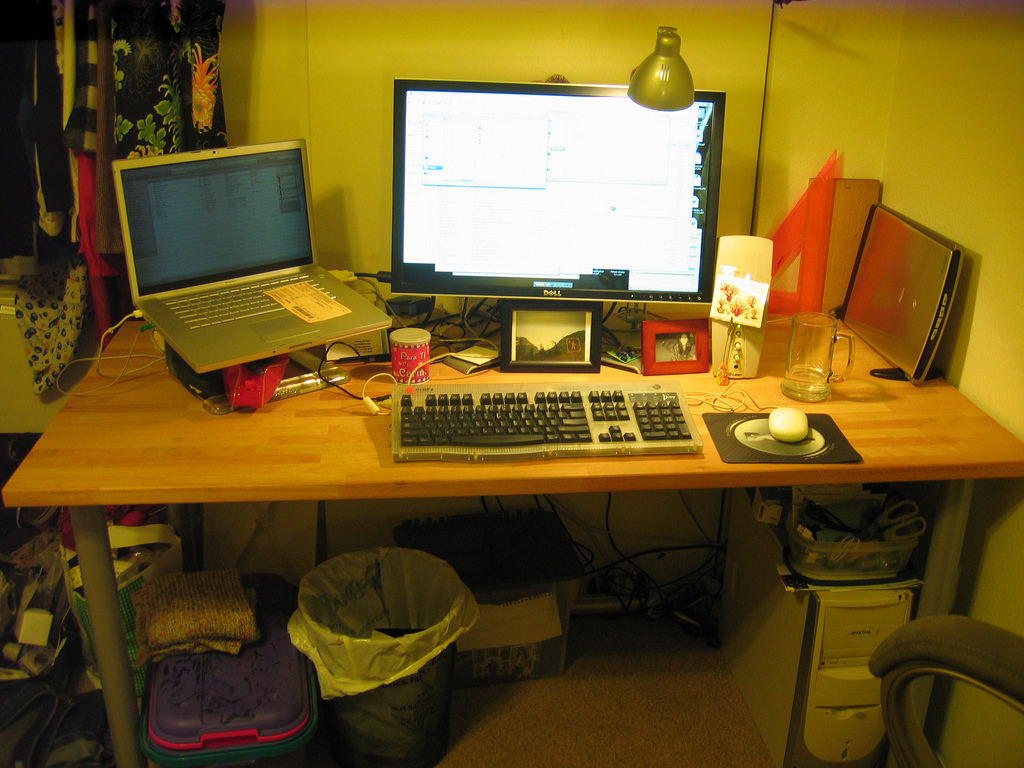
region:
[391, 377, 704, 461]
an extended computer keyboard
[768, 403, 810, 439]
an Apple Mighty Mouse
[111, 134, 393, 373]
an open laptop computer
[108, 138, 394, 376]
an Apple MacBook Pro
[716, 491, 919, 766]
a white desktop tower PC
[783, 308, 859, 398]
a clear glass mug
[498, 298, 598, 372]
a black framed photo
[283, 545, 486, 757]
trash bag in the garbage can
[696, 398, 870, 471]
mouse is on a mousepad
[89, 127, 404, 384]
laptop is silver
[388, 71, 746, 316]
computer monitor is on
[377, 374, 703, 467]
black keys on a silver keyboard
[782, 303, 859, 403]
empty glass that has a handle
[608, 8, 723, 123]
lamp is hanging over the monitor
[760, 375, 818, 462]
a white mighty mouse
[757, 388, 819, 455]
a white computer mouse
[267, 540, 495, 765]
this is a wastebasket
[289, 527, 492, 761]
there is a plastic bag in the wastebasket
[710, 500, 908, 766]
this is an old computer tower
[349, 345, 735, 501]
the keyboard has black keys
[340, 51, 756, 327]
a widescreen computer monitor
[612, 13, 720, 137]
this is a silver desk lamp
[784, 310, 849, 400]
A glass mug on the table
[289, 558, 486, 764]
A trashcan under the desk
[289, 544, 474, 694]
A plastic bag in the trashcan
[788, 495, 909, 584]
A plastic container on the computer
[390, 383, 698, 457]
A gray and black keyboard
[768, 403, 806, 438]
A white computer mouse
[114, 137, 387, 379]
A silver laptop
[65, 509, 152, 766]
The metal leg of the desk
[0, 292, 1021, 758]
A wooden desk against the wall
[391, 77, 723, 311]
a computer monitor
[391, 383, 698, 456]
a computer keyboard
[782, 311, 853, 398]
a clear empty glass mug on a desk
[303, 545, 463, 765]
a garbage can under a desk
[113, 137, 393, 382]
an open laptop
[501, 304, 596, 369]
picture of a mountain under a monitor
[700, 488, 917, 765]
a computer under a desk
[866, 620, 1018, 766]
the arm of a desk chair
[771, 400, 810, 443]
a mouse on a black mouse pad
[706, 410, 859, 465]
a black mousepad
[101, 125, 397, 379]
lap top on a desk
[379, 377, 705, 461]
silver and black keyboard on desk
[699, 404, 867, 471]
black mouse pad with DELL Logo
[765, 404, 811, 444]
white mouse on mouse pad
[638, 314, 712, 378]
snap shot in a red photo frame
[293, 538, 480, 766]
garbage can lined with a white bag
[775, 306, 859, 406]
an empty glass beer mug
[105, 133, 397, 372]
open laptop computer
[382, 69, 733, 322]
large desktop monitor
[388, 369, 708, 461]
grey and black keyboard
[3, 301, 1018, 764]
brown table filled with computers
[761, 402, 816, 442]
a white computer mouse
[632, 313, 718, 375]
red picture frame with a photo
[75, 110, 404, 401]
this is a macbook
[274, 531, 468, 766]
a small garbage can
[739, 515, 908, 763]
this is a white and grey computer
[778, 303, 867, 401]
a clear glass mug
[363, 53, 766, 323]
this is a widescreen computer monitor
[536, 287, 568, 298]
this is the Dell logo